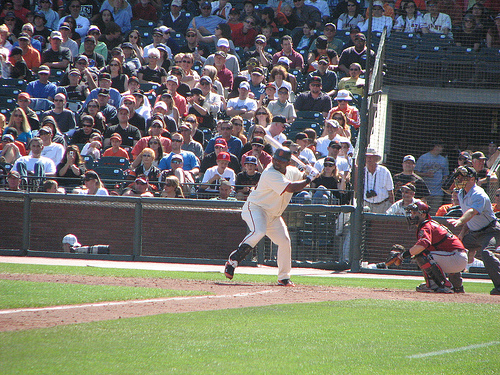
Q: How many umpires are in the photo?
A: One.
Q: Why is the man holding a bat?
A: To hit ball.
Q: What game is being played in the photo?
A: Baseball.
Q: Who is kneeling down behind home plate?
A: The catcher.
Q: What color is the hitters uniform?
A: White.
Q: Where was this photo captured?
A: At a baseball field.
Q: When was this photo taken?
A: In the daytime.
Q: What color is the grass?
A: Green.